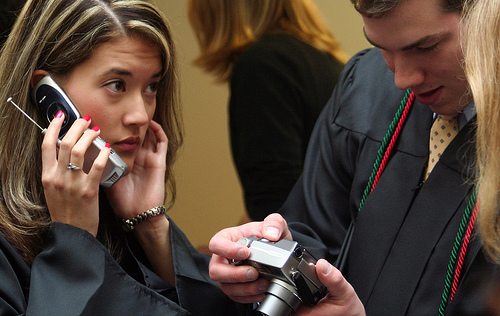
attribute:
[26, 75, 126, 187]
cell phone — flip, grey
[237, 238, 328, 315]
camera — gray, handheld, metal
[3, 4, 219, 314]
woman — standing, young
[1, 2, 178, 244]
hair — highlighted, blonde, brown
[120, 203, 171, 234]
bracelet — twisted, metal, gold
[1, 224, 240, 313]
jacket — black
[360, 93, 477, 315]
cord — green, red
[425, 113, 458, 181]
tie — grey, gold, black